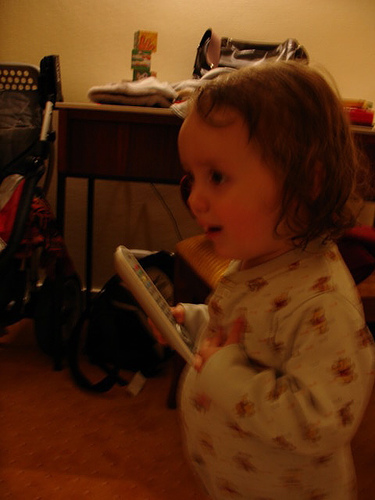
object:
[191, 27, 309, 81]
strap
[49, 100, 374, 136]
table top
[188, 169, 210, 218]
nose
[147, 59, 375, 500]
baby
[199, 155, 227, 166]
eyebrow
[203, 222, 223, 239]
mouth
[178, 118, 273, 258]
face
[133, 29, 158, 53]
block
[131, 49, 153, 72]
block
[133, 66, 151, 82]
block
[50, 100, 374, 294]
table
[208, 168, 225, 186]
eye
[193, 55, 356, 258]
hair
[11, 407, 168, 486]
carpet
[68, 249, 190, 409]
bag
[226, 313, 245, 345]
thumb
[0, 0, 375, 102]
wall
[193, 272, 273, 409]
chest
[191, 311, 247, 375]
child's hand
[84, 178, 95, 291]
legs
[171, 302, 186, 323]
thumb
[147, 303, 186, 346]
hand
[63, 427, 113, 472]
ground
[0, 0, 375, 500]
house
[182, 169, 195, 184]
eye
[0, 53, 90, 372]
stroller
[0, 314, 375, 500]
floor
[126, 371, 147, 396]
tag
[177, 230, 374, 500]
clothing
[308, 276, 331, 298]
design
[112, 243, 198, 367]
controller